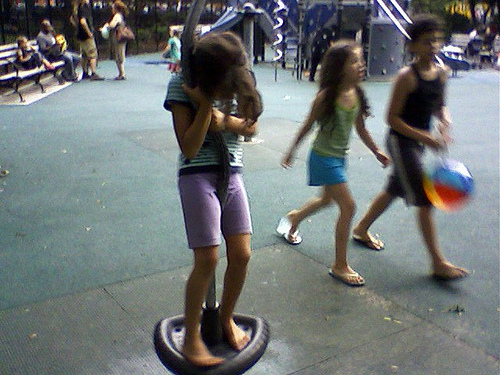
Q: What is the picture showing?
A: It is showing a park.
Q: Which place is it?
A: It is a park.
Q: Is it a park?
A: Yes, it is a park.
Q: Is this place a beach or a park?
A: It is a park.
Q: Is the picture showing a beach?
A: No, the picture is showing a park.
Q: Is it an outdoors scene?
A: Yes, it is outdoors.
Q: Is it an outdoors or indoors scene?
A: It is outdoors.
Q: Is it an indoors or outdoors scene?
A: It is outdoors.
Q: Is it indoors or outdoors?
A: It is outdoors.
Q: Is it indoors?
A: No, it is outdoors.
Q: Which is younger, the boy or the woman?
A: The boy is younger than the woman.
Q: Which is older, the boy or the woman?
A: The woman is older than the boy.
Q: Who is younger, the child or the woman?
A: The child is younger than the woman.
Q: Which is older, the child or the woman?
A: The woman is older than the child.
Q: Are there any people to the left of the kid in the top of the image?
A: Yes, there is a person to the left of the kid.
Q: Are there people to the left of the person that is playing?
A: Yes, there is a person to the left of the kid.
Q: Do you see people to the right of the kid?
A: No, the person is to the left of the kid.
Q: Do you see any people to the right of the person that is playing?
A: No, the person is to the left of the kid.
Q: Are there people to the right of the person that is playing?
A: No, the person is to the left of the kid.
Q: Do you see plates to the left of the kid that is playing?
A: No, there is a person to the left of the child.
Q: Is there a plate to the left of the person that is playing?
A: No, there is a person to the left of the child.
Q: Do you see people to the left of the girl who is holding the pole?
A: Yes, there is a person to the left of the girl.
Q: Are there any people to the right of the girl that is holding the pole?
A: No, the person is to the left of the girl.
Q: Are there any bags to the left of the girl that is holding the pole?
A: No, there is a person to the left of the girl.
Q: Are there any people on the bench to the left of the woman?
A: Yes, there is a person on the bench.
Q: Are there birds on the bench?
A: No, there is a person on the bench.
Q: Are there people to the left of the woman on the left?
A: Yes, there is a person to the left of the woman.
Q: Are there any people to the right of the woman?
A: No, the person is to the left of the woman.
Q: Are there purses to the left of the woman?
A: No, there is a person to the left of the woman.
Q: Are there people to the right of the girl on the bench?
A: Yes, there is a person to the right of the girl.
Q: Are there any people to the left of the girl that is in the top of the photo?
A: No, the person is to the right of the girl.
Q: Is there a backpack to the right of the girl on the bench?
A: No, there is a person to the right of the girl.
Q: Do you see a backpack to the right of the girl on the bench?
A: No, there is a person to the right of the girl.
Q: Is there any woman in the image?
A: Yes, there is a woman.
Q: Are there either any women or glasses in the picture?
A: Yes, there is a woman.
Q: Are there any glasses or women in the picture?
A: Yes, there is a woman.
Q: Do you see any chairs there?
A: No, there are no chairs.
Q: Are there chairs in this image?
A: No, there are no chairs.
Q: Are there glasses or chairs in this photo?
A: No, there are no chairs or glasses.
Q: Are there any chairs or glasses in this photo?
A: No, there are no chairs or glasses.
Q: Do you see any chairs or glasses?
A: No, there are no chairs or glasses.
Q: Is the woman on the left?
A: Yes, the woman is on the left of the image.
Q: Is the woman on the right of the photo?
A: No, the woman is on the left of the image.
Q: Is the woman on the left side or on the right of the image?
A: The woman is on the left of the image.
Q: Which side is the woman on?
A: The woman is on the left of the image.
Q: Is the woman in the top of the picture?
A: Yes, the woman is in the top of the image.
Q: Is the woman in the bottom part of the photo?
A: No, the woman is in the top of the image.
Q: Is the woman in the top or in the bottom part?
A: The woman is in the top of the image.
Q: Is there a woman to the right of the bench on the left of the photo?
A: Yes, there is a woman to the right of the bench.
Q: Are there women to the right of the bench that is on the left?
A: Yes, there is a woman to the right of the bench.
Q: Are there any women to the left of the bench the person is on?
A: No, the woman is to the right of the bench.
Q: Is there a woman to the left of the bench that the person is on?
A: No, the woman is to the right of the bench.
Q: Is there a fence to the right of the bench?
A: No, there is a woman to the right of the bench.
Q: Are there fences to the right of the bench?
A: No, there is a woman to the right of the bench.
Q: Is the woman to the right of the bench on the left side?
A: Yes, the woman is to the right of the bench.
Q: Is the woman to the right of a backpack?
A: No, the woman is to the right of the bench.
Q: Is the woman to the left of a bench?
A: No, the woman is to the right of a bench.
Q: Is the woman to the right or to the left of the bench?
A: The woman is to the right of the bench.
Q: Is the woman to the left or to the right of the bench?
A: The woman is to the right of the bench.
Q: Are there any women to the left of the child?
A: Yes, there is a woman to the left of the child.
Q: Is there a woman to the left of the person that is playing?
A: Yes, there is a woman to the left of the child.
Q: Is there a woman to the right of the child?
A: No, the woman is to the left of the child.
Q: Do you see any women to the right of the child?
A: No, the woman is to the left of the child.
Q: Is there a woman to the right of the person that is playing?
A: No, the woman is to the left of the child.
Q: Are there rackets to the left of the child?
A: No, there is a woman to the left of the child.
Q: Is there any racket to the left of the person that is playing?
A: No, there is a woman to the left of the child.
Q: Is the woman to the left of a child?
A: Yes, the woman is to the left of a child.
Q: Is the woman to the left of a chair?
A: No, the woman is to the left of a child.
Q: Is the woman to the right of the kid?
A: No, the woman is to the left of the kid.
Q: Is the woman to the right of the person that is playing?
A: No, the woman is to the left of the kid.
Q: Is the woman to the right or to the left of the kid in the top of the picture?
A: The woman is to the left of the child.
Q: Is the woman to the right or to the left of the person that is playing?
A: The woman is to the left of the child.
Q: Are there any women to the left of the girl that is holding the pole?
A: Yes, there is a woman to the left of the girl.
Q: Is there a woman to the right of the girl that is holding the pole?
A: No, the woman is to the left of the girl.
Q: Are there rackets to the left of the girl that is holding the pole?
A: No, there is a woman to the left of the girl.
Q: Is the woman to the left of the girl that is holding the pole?
A: Yes, the woman is to the left of the girl.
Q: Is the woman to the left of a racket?
A: No, the woman is to the left of the girl.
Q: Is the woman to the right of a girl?
A: No, the woman is to the left of a girl.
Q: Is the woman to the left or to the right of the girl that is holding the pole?
A: The woman is to the left of the girl.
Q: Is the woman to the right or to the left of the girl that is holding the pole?
A: The woman is to the left of the girl.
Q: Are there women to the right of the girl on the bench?
A: Yes, there is a woman to the right of the girl.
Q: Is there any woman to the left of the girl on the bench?
A: No, the woman is to the right of the girl.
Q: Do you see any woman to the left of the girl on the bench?
A: No, the woman is to the right of the girl.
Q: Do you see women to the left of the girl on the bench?
A: No, the woman is to the right of the girl.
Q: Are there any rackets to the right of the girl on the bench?
A: No, there is a woman to the right of the girl.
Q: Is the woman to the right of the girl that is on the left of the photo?
A: Yes, the woman is to the right of the girl.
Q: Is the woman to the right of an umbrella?
A: No, the woman is to the right of the girl.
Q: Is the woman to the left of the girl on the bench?
A: No, the woman is to the right of the girl.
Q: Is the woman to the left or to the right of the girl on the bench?
A: The woman is to the right of the girl.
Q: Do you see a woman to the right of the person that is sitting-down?
A: Yes, there is a woman to the right of the person.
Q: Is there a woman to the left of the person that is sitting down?
A: No, the woman is to the right of the person.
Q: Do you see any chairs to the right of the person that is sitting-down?
A: No, there is a woman to the right of the person.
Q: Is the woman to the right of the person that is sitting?
A: Yes, the woman is to the right of the person.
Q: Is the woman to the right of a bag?
A: No, the woman is to the right of the person.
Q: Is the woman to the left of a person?
A: No, the woman is to the right of a person.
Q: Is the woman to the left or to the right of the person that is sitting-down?
A: The woman is to the right of the person.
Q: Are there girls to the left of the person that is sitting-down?
A: Yes, there is a girl to the left of the person.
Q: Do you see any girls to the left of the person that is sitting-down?
A: Yes, there is a girl to the left of the person.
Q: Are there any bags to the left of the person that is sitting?
A: No, there is a girl to the left of the person.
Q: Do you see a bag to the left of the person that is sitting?
A: No, there is a girl to the left of the person.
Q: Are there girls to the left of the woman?
A: Yes, there is a girl to the left of the woman.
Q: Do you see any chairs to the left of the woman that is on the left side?
A: No, there is a girl to the left of the woman.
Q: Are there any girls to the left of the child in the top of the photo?
A: Yes, there is a girl to the left of the kid.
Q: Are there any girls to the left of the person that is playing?
A: Yes, there is a girl to the left of the kid.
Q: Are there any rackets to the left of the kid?
A: No, there is a girl to the left of the kid.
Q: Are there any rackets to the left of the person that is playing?
A: No, there is a girl to the left of the kid.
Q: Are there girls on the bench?
A: Yes, there is a girl on the bench.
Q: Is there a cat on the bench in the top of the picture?
A: No, there is a girl on the bench.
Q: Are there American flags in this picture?
A: No, there are no American flags.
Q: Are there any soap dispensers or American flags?
A: No, there are no American flags or soap dispensers.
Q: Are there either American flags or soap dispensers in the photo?
A: No, there are no American flags or soap dispensers.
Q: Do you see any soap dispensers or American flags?
A: No, there are no American flags or soap dispensers.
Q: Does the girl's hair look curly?
A: Yes, the hair is curly.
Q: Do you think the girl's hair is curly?
A: Yes, the hair is curly.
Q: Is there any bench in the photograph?
A: Yes, there is a bench.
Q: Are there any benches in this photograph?
A: Yes, there is a bench.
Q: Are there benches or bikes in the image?
A: Yes, there is a bench.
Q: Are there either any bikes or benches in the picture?
A: Yes, there is a bench.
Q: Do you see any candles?
A: No, there are no candles.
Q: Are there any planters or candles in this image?
A: No, there are no candles or planters.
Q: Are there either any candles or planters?
A: No, there are no candles or planters.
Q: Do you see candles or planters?
A: No, there are no candles or planters.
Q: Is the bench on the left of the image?
A: Yes, the bench is on the left of the image.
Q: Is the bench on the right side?
A: No, the bench is on the left of the image.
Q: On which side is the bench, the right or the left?
A: The bench is on the left of the image.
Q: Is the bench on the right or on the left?
A: The bench is on the left of the image.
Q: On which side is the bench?
A: The bench is on the left of the image.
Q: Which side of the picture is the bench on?
A: The bench is on the left of the image.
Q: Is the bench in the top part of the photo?
A: Yes, the bench is in the top of the image.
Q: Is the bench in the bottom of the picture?
A: No, the bench is in the top of the image.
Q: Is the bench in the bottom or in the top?
A: The bench is in the top of the image.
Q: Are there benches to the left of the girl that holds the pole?
A: Yes, there is a bench to the left of the girl.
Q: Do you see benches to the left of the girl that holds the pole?
A: Yes, there is a bench to the left of the girl.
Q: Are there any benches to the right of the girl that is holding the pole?
A: No, the bench is to the left of the girl.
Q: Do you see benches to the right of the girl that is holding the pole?
A: No, the bench is to the left of the girl.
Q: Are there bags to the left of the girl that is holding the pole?
A: No, there is a bench to the left of the girl.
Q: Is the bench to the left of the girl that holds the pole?
A: Yes, the bench is to the left of the girl.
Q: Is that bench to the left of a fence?
A: No, the bench is to the left of the girl.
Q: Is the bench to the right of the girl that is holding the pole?
A: No, the bench is to the left of the girl.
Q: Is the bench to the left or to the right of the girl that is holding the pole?
A: The bench is to the left of the girl.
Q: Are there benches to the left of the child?
A: Yes, there is a bench to the left of the child.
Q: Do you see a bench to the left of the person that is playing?
A: Yes, there is a bench to the left of the child.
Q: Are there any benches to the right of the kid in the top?
A: No, the bench is to the left of the kid.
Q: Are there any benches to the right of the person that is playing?
A: No, the bench is to the left of the kid.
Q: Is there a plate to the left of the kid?
A: No, there is a bench to the left of the kid.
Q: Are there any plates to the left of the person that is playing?
A: No, there is a bench to the left of the kid.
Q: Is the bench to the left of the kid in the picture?
A: Yes, the bench is to the left of the kid.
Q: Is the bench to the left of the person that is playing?
A: Yes, the bench is to the left of the kid.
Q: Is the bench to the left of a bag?
A: No, the bench is to the left of the kid.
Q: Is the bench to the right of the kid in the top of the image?
A: No, the bench is to the left of the kid.